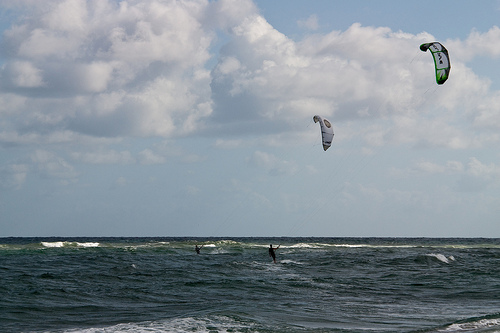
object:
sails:
[313, 114, 334, 151]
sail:
[419, 42, 450, 86]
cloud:
[10, 155, 30, 189]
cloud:
[8, 102, 65, 132]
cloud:
[82, 92, 170, 142]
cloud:
[106, 19, 173, 74]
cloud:
[217, 53, 261, 113]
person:
[268, 244, 281, 265]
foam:
[44, 315, 260, 332]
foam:
[0, 240, 500, 251]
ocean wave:
[278, 242, 390, 248]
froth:
[426, 253, 456, 264]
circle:
[324, 119, 332, 128]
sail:
[301, 100, 340, 157]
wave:
[211, 262, 443, 293]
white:
[312, 114, 334, 152]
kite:
[313, 114, 335, 151]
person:
[195, 244, 204, 254]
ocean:
[0, 236, 500, 333]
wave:
[1, 236, 498, 263]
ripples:
[73, 261, 211, 309]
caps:
[41, 241, 100, 248]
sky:
[0, 0, 498, 239]